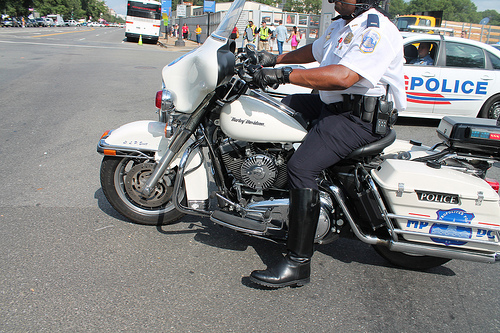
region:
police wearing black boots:
[248, 253, 320, 284]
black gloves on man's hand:
[253, 63, 296, 91]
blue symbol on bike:
[413, 201, 488, 251]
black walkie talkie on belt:
[376, 83, 400, 139]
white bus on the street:
[118, 4, 168, 55]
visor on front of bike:
[196, 0, 267, 43]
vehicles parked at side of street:
[4, 8, 84, 32]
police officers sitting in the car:
[403, 35, 451, 67]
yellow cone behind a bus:
[131, 28, 150, 49]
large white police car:
[403, 18, 498, 120]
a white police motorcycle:
[91, 1, 498, 278]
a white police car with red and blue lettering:
[379, 27, 499, 135]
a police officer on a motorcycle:
[218, 0, 404, 302]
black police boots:
[228, 180, 323, 296]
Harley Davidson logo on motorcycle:
[221, 106, 270, 134]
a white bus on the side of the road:
[113, 1, 170, 46]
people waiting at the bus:
[162, 13, 203, 41]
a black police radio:
[370, 81, 395, 142]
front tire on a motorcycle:
[91, 116, 203, 226]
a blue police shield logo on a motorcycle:
[423, 205, 475, 252]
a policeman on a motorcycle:
[97, 0, 497, 287]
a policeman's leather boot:
[248, 189, 319, 289]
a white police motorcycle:
[96, 0, 498, 267]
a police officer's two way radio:
[370, 85, 394, 135]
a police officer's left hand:
[249, 64, 284, 91]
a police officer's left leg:
[248, 114, 388, 289]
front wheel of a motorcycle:
[101, 154, 186, 225]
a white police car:
[399, 25, 499, 117]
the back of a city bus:
[125, 0, 160, 41]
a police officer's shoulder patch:
[365, 11, 379, 28]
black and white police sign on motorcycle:
[420, 189, 462, 204]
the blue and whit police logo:
[429, 207, 475, 244]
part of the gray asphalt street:
[15, 217, 143, 316]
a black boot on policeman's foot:
[248, 192, 311, 296]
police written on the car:
[410, 72, 490, 100]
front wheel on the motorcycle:
[98, 150, 173, 225]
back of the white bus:
[127, 2, 155, 39]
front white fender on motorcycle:
[101, 122, 170, 147]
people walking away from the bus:
[175, 19, 204, 44]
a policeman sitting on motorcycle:
[96, 0, 498, 293]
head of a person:
[329, 0, 373, 24]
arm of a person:
[270, 49, 358, 94]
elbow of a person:
[329, 68, 384, 98]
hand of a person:
[247, 42, 305, 93]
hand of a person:
[249, 52, 280, 64]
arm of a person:
[276, 36, 337, 71]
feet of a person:
[210, 255, 327, 297]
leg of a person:
[260, 135, 368, 255]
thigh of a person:
[289, 103, 396, 168]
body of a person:
[307, 11, 409, 106]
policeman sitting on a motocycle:
[248, 2, 408, 289]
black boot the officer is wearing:
[251, 252, 315, 289]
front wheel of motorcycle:
[98, 122, 206, 226]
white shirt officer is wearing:
[317, 9, 406, 109]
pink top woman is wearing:
[289, 31, 299, 46]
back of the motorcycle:
[368, 114, 498, 266]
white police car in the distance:
[271, 31, 496, 126]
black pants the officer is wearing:
[270, 100, 390, 258]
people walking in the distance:
[161, 14, 309, 57]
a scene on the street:
[3, 3, 495, 330]